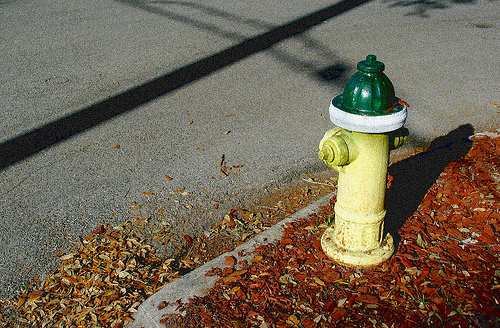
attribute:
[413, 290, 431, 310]
grass — green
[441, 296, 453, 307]
grass — green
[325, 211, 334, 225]
grass — green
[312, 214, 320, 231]
grass — green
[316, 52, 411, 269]
hydrant — white, green, yellow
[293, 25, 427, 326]
hydrant — green, yellow , white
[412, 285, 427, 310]
grass — green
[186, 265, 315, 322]
mulch — brown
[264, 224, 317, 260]
mulch — brown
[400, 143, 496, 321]
mulch — brown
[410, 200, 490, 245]
mulch — brown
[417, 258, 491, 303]
mulch — brown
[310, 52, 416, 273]
fire hydrant — green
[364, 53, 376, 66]
bolt — green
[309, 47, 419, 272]
hydrant — yellow, green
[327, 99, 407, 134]
trim — white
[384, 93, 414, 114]
leaves — small